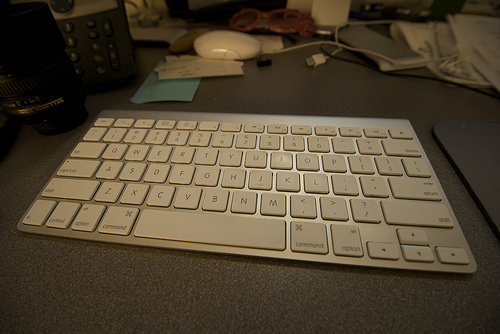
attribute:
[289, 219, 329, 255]
button — white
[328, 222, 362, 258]
button — white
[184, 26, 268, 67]
computer mouse — white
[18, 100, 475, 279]
keyboard — white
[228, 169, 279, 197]
keyboard button — white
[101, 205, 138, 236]
keyboard button — white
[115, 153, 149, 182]
button — white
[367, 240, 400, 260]
keys — arrow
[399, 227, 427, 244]
keys — arrow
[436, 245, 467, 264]
keys — arrow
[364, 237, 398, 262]
button — white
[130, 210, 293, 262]
button — white